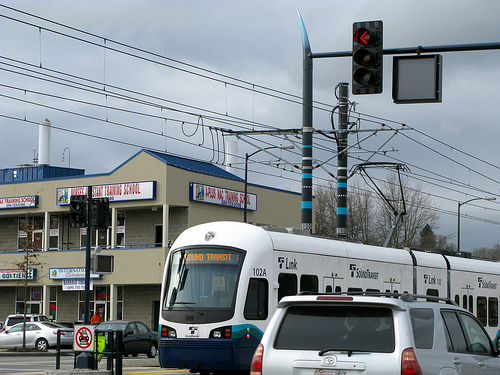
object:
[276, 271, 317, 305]
door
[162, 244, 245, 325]
windshield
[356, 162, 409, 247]
rail connection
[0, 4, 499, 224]
overhead wires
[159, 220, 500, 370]
train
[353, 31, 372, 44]
arrow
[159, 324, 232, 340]
headlights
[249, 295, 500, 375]
car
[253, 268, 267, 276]
id number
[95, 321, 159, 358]
car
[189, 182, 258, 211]
sign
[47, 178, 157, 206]
sign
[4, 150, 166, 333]
facade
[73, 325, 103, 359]
sign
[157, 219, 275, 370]
train front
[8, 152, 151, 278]
tan building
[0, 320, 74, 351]
car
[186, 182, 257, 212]
store sign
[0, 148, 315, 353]
building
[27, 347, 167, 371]
road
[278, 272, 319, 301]
window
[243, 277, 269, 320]
side window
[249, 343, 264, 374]
tail light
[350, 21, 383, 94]
traffic light